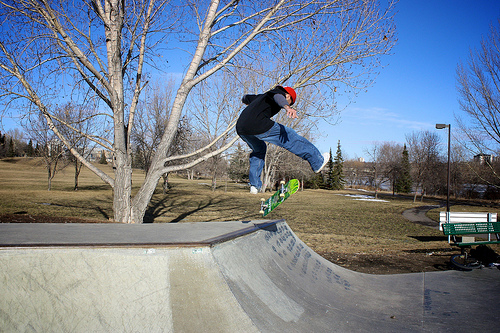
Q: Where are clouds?
A: In the sky.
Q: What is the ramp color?
A: Gray.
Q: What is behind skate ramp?
A: Tree.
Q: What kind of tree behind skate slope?
A: Bare.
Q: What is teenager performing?
A: Skateboarding trick.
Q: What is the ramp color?
A: Gray.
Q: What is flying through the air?
A: Skateboarder.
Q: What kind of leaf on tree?
A: Leafless.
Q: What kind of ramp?
A: Cement.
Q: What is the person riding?
A: A skateboard.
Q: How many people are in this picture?
A: One.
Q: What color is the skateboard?
A: Green.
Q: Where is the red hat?
A: On the person's head.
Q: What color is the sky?
A: Blue.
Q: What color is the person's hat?
A: Red.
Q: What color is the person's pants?
A: Blue.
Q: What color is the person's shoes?
A: White.